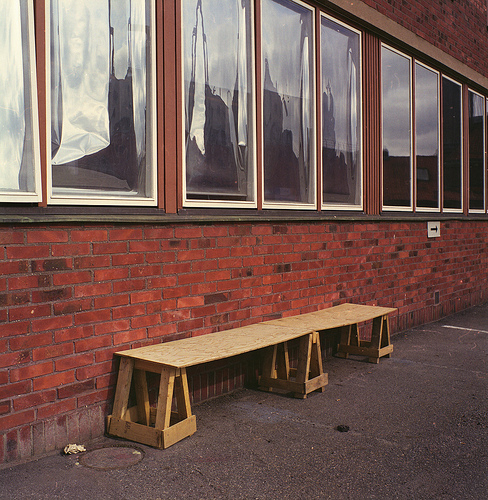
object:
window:
[381, 40, 466, 213]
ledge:
[60, 212, 423, 224]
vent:
[431, 289, 442, 307]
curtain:
[189, 12, 249, 155]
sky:
[385, 71, 436, 143]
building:
[416, 154, 439, 206]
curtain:
[266, 36, 313, 154]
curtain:
[326, 65, 361, 161]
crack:
[406, 348, 477, 384]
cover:
[79, 443, 145, 471]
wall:
[0, 223, 487, 465]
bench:
[104, 301, 399, 450]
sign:
[425, 220, 443, 238]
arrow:
[427, 223, 439, 234]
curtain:
[50, 11, 112, 167]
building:
[0, 0, 487, 303]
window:
[43, 4, 157, 204]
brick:
[31, 255, 78, 273]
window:
[184, 0, 363, 208]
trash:
[62, 440, 87, 455]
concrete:
[232, 411, 479, 499]